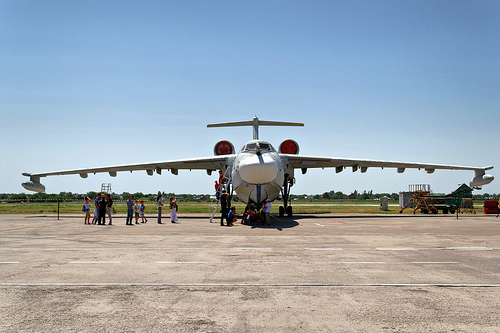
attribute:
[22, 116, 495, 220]
plane — white, wide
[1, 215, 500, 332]
ground — dirty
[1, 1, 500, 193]
sky — blue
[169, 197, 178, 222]
person — standing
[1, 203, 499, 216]
grass — green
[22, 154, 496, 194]
wings — long